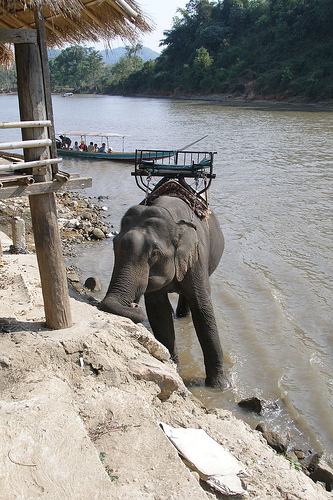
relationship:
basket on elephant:
[135, 151, 227, 190] [103, 201, 235, 370]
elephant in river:
[103, 201, 235, 370] [246, 129, 284, 170]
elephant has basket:
[103, 201, 235, 370] [135, 151, 227, 190]